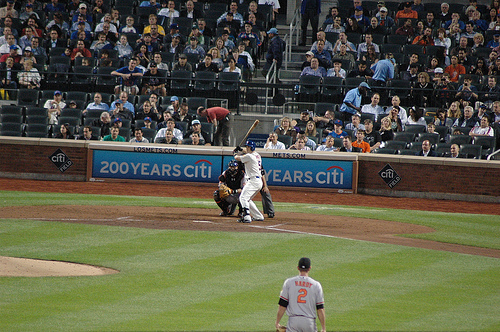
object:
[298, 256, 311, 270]
baseball cap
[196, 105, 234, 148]
fan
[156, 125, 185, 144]
fan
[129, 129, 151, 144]
fan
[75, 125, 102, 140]
fan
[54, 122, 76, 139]
fan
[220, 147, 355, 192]
sign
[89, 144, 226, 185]
sign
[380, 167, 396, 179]
citi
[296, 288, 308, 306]
number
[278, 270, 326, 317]
shirt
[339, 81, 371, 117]
man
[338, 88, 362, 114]
shirt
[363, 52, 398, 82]
man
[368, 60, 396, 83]
shirt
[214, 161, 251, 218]
catcher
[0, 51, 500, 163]
stands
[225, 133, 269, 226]
batter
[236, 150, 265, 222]
white uniform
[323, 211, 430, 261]
brown bear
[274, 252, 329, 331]
athlete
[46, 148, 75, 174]
triangle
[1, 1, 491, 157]
crowd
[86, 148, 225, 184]
window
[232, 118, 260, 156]
bat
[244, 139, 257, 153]
helmet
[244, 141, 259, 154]
head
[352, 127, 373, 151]
man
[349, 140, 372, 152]
shirt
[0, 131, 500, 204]
wall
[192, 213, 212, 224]
home plate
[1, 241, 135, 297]
pitcher's mound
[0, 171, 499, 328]
ball field